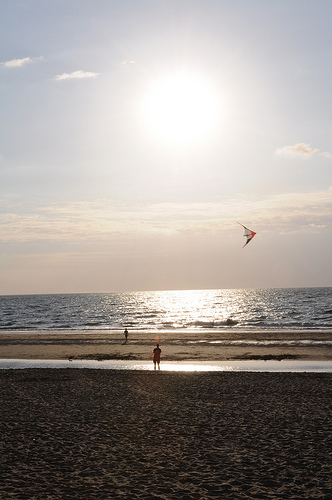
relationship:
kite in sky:
[237, 221, 255, 247] [87, 134, 215, 172]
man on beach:
[148, 338, 169, 371] [38, 170, 331, 474]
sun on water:
[133, 283, 298, 335] [0, 286, 330, 339]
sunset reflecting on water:
[113, 289, 281, 338] [10, 294, 324, 321]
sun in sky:
[142, 74, 218, 155] [1, 1, 330, 296]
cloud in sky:
[271, 138, 319, 161] [1, 1, 330, 296]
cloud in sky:
[53, 68, 99, 83] [1, 1, 330, 296]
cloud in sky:
[1, 53, 34, 72] [1, 1, 330, 296]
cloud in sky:
[271, 143, 329, 161] [1, 1, 330, 296]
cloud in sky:
[113, 53, 137, 71] [1, 1, 330, 296]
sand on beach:
[0, 368, 327, 493] [5, 327, 331, 492]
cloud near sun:
[271, 143, 329, 161] [162, 91, 229, 146]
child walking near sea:
[121, 327, 128, 341] [0, 286, 331, 332]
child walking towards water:
[123, 327, 128, 339] [0, 287, 331, 371]